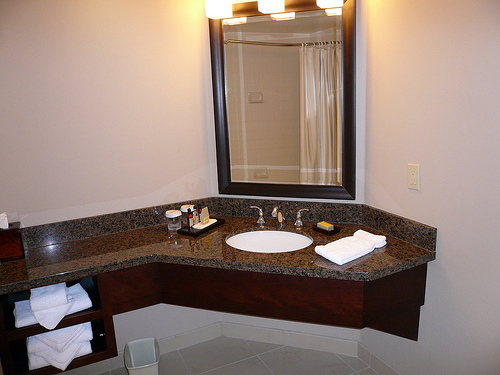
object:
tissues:
[0, 222, 26, 262]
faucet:
[275, 209, 286, 226]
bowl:
[225, 230, 314, 254]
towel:
[314, 229, 387, 266]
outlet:
[407, 164, 420, 191]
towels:
[12, 282, 95, 329]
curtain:
[299, 41, 344, 187]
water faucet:
[271, 204, 279, 218]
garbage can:
[124, 337, 162, 375]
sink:
[225, 230, 312, 253]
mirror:
[220, 14, 346, 187]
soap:
[316, 221, 334, 231]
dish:
[312, 225, 340, 235]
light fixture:
[205, 2, 233, 20]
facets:
[210, 197, 365, 226]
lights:
[223, 17, 247, 26]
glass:
[165, 209, 182, 230]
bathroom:
[3, 0, 499, 375]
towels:
[29, 282, 74, 329]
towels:
[25, 322, 98, 371]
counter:
[0, 216, 437, 295]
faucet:
[249, 206, 265, 224]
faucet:
[294, 208, 310, 228]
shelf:
[6, 276, 122, 373]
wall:
[0, 0, 497, 361]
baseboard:
[113, 311, 358, 373]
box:
[0, 220, 26, 264]